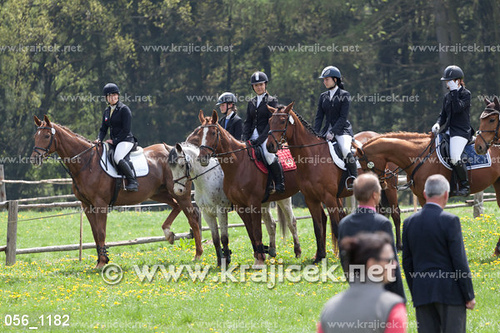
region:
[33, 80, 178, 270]
brown horse standing on grass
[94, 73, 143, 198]
rider on a horse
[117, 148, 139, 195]
boot on a rider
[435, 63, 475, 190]
rider on a horse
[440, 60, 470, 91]
helmet on a rider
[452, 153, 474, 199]
boot on a rider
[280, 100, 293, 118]
ear on a horse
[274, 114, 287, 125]
eye on a horse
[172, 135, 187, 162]
ear on a horse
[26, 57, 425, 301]
Horses on the grass.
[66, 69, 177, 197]
jockey on the horse.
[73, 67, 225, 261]
Jockey on a brown horse.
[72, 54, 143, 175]
Helmet on the jockey.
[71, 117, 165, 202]
Saddle on the horse.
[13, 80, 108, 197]
Reins on the horse.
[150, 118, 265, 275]
White horse on the grass.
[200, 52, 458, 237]
People on horses.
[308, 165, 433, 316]
Men in suits.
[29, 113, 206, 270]
a brown horse in field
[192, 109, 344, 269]
a brown horse in field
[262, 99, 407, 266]
a brown horse in field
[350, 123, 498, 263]
a brown horse in field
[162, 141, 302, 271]
a white and black spotted horse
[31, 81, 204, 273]
a person riding a horse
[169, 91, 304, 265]
a person riding a horse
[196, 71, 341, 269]
a person riding a horse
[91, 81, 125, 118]
the head of a man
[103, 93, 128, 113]
the chin of a man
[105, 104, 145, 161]
the arm of a man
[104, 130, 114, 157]
the hand of a man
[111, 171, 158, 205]
the leg of a man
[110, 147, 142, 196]
the knee of a man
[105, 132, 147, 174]
the leg of a man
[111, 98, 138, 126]
the shoulder of a man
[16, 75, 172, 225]
woman wearing a helmet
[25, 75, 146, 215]
woman wearing black jacket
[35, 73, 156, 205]
woman wearing white pants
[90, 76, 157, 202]
woman wearing black boots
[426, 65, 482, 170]
woman wearing a helmet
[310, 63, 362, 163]
woman wearing a helmet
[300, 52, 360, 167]
woman wearing black jacket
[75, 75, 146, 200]
woman sitting on a horse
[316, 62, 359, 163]
woman sitting on a horse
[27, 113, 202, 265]
A horse standing in the grass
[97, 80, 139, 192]
A rider on top of a horse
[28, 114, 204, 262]
a horse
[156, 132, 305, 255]
a horse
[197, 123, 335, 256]
a horse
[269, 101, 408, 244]
a horse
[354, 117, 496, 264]
a horse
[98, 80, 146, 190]
a person is sitting down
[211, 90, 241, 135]
a person is sitting down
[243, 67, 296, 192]
a person is sitting down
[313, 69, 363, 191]
a person is sitting down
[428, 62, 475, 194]
a person is sitting down